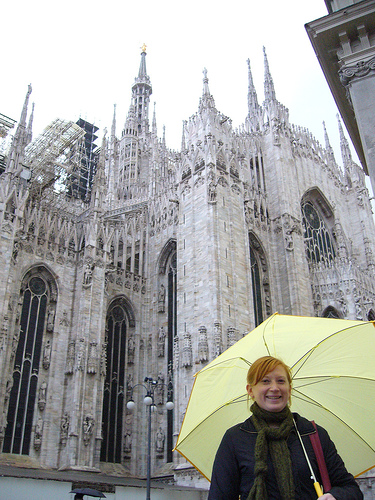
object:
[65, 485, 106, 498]
umbrella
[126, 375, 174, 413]
lamp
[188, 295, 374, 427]
umbrella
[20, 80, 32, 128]
spire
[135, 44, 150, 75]
spire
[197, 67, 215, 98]
spire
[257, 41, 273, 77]
spire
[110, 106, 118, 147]
spire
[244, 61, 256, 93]
spire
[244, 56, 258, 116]
tower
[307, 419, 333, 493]
red strap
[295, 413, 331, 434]
shoulder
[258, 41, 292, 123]
tower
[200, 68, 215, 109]
point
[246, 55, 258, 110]
point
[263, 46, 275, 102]
point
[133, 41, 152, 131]
point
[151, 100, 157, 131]
point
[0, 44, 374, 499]
building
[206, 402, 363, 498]
jacket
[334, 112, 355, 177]
spire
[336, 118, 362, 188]
tower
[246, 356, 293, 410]
hair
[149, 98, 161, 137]
spire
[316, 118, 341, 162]
spire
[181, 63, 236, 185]
tower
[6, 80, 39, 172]
tower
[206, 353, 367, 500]
girl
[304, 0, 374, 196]
building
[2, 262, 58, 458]
window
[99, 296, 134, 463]
window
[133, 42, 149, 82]
spire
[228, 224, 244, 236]
brick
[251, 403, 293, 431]
neck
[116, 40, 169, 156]
tower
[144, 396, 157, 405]
light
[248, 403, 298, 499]
scarf